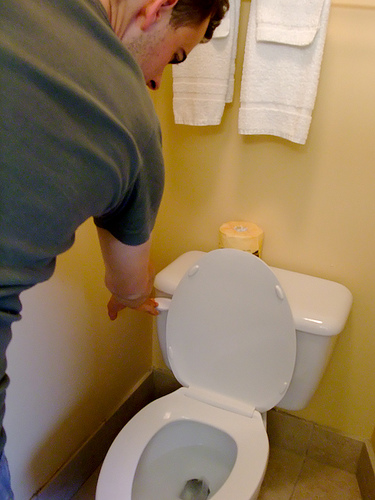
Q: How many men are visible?
A: One.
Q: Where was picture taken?
A: Bathroom.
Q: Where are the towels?
A: Hung up.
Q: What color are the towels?
A: White.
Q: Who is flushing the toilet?
A: The man.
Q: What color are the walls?
A: Yellow.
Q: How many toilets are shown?
A: One.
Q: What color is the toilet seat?
A: White.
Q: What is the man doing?
A: Flushing the toilet.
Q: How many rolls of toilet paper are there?
A: 1.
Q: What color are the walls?
A: Yellow.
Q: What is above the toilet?
A: Hand towels.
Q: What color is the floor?
A: Light brown.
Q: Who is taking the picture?
A: A friend.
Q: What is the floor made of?
A: Tiles.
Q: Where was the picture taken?
A: The picture was taken inside.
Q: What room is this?
A: The bathroom.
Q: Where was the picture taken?
A: In a bathroom.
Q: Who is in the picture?
A: A man.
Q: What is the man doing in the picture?
A: Flushing the toilet.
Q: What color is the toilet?
A: White.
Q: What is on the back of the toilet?
A: Toilet paper.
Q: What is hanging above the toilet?
A: Towels.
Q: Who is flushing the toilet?
A: The man in the gray shirt.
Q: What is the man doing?
A: Flushing a toilet.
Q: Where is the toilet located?
A: In the restroom.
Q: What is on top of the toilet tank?
A: A roll of tissue.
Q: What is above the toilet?
A: Towels.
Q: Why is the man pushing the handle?
A: To flush the water.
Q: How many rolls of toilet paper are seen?
A: 1.